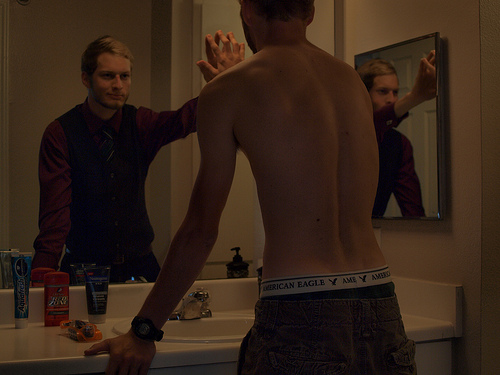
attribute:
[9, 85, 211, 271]
shirt — maroon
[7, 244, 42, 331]
toothpaste — standing upright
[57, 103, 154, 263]
vest — blue, black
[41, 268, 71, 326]
deodorant — roll on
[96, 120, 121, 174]
tie — striped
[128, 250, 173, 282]
pants — black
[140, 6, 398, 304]
man — shirtless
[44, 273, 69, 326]
container — red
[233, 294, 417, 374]
pants — brown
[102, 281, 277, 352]
sink — white, porcelain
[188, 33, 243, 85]
hands — touching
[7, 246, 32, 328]
tube — blue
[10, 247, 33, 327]
toothpaste — large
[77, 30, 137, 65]
hair — short